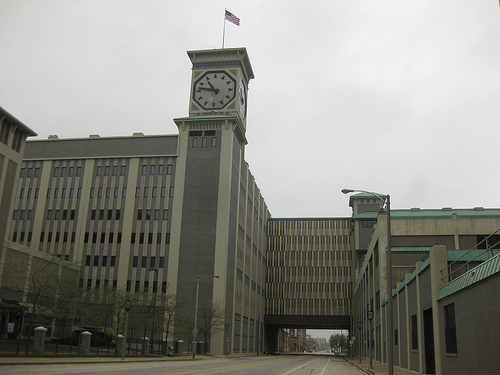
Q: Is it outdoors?
A: Yes, it is outdoors.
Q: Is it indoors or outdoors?
A: It is outdoors.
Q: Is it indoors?
A: No, it is outdoors.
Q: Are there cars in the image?
A: No, there are no cars.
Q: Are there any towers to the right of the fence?
A: Yes, there is a tower to the right of the fence.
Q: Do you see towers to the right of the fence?
A: Yes, there is a tower to the right of the fence.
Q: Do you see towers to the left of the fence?
A: No, the tower is to the right of the fence.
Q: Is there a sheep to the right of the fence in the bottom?
A: No, there is a tower to the right of the fence.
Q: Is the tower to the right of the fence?
A: Yes, the tower is to the right of the fence.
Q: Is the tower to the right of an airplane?
A: No, the tower is to the right of the fence.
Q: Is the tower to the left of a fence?
A: No, the tower is to the right of a fence.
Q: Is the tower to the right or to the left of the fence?
A: The tower is to the right of the fence.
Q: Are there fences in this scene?
A: Yes, there is a fence.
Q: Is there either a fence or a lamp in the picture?
A: Yes, there is a fence.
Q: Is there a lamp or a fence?
A: Yes, there is a fence.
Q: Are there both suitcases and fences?
A: No, there is a fence but no suitcases.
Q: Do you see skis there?
A: No, there are no skis.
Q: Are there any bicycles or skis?
A: No, there are no skis or bicycles.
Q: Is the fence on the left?
A: Yes, the fence is on the left of the image.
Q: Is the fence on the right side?
A: No, the fence is on the left of the image.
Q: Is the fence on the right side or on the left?
A: The fence is on the left of the image.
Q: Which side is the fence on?
A: The fence is on the left of the image.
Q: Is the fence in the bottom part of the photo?
A: Yes, the fence is in the bottom of the image.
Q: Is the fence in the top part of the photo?
A: No, the fence is in the bottom of the image.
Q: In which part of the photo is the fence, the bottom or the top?
A: The fence is in the bottom of the image.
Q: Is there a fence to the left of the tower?
A: Yes, there is a fence to the left of the tower.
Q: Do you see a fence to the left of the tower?
A: Yes, there is a fence to the left of the tower.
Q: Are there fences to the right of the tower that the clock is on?
A: No, the fence is to the left of the tower.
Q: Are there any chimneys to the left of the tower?
A: No, there is a fence to the left of the tower.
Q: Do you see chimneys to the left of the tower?
A: No, there is a fence to the left of the tower.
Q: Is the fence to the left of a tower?
A: Yes, the fence is to the left of a tower.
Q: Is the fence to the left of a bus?
A: No, the fence is to the left of a tower.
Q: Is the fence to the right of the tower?
A: No, the fence is to the left of the tower.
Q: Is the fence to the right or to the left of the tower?
A: The fence is to the left of the tower.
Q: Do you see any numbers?
A: Yes, there are numbers.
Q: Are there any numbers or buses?
A: Yes, there are numbers.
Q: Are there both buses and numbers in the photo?
A: No, there are numbers but no buses.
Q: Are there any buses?
A: No, there are no buses.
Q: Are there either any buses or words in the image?
A: No, there are no buses or words.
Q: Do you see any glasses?
A: No, there are no glasses.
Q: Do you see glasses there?
A: No, there are no glasses.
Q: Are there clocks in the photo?
A: Yes, there is a clock.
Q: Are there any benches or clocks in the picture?
A: Yes, there is a clock.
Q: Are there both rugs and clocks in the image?
A: No, there is a clock but no rugs.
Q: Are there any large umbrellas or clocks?
A: Yes, there is a large clock.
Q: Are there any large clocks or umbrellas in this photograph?
A: Yes, there is a large clock.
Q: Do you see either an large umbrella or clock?
A: Yes, there is a large clock.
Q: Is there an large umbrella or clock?
A: Yes, there is a large clock.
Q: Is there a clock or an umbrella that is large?
A: Yes, the clock is large.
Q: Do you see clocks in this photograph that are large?
A: Yes, there is a large clock.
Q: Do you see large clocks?
A: Yes, there is a large clock.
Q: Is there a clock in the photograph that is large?
A: Yes, there is a clock that is large.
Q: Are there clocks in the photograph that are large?
A: Yes, there is a clock that is large.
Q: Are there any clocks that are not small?
A: Yes, there is a large clock.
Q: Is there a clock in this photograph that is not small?
A: Yes, there is a large clock.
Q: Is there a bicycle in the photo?
A: No, there are no bicycles.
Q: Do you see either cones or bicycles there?
A: No, there are no bicycles or cones.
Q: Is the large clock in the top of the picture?
A: Yes, the clock is in the top of the image.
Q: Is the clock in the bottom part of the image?
A: No, the clock is in the top of the image.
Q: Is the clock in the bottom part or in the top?
A: The clock is in the top of the image.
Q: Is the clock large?
A: Yes, the clock is large.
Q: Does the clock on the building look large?
A: Yes, the clock is large.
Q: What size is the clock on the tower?
A: The clock is large.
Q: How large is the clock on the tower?
A: The clock is large.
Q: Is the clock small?
A: No, the clock is large.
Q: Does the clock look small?
A: No, the clock is large.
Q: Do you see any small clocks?
A: No, there is a clock but it is large.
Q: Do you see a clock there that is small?
A: No, there is a clock but it is large.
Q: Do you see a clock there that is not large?
A: No, there is a clock but it is large.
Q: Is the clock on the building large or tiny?
A: The clock is large.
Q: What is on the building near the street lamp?
A: The clock is on the building.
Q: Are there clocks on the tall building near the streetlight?
A: Yes, there is a clock on the building.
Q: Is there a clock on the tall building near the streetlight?
A: Yes, there is a clock on the building.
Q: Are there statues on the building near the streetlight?
A: No, there is a clock on the building.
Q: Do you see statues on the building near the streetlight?
A: No, there is a clock on the building.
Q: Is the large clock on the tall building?
A: Yes, the clock is on the building.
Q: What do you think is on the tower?
A: The clock is on the tower.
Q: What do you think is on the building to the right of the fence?
A: The clock is on the tower.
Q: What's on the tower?
A: The clock is on the tower.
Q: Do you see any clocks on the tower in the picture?
A: Yes, there is a clock on the tower.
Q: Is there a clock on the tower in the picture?
A: Yes, there is a clock on the tower.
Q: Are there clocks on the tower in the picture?
A: Yes, there is a clock on the tower.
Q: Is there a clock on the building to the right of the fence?
A: Yes, there is a clock on the tower.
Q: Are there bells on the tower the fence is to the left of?
A: No, there is a clock on the tower.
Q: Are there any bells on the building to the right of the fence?
A: No, there is a clock on the tower.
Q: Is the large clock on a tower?
A: Yes, the clock is on a tower.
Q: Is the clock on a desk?
A: No, the clock is on a tower.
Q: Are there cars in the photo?
A: No, there are no cars.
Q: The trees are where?
A: The trees are on the sidewalk.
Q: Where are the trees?
A: The trees are on the sidewalk.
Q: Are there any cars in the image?
A: No, there are no cars.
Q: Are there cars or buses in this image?
A: No, there are no cars or buses.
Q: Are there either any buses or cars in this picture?
A: No, there are no cars or buses.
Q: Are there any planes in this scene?
A: No, there are no planes.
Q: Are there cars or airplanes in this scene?
A: No, there are no airplanes or cars.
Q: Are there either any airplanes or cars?
A: No, there are no airplanes or cars.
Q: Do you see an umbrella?
A: No, there are no umbrellas.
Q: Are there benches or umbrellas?
A: No, there are no umbrellas or benches.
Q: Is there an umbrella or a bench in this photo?
A: No, there are no umbrellas or benches.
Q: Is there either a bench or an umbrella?
A: No, there are no umbrellas or benches.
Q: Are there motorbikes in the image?
A: No, there are no motorbikes.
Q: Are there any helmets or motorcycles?
A: No, there are no motorcycles or helmets.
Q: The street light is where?
A: The street light is on the sidewalk.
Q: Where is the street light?
A: The street light is on the sidewalk.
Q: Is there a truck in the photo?
A: No, there are no trucks.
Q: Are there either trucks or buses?
A: No, there are no trucks or buses.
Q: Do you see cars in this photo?
A: No, there are no cars.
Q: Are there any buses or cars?
A: No, there are no cars or buses.